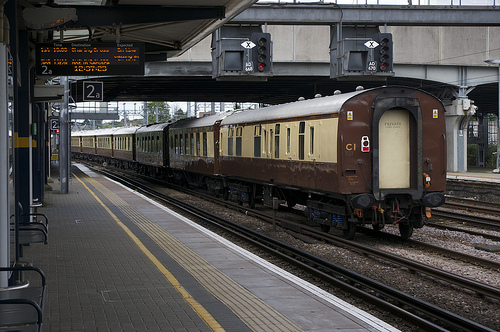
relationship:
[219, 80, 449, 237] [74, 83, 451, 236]
car on car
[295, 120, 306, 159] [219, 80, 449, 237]
window on car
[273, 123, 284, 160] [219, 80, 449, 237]
window on car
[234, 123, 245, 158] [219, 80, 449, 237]
window on car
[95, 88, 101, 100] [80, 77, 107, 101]
letter on sign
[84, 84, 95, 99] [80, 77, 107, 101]
number on sign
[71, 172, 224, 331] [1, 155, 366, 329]
line painted on platform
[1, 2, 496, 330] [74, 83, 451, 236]
station for train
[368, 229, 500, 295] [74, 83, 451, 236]
tracks for train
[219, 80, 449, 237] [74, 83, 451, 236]
car on train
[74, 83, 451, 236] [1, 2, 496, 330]
train leaving station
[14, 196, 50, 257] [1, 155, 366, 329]
bench on platform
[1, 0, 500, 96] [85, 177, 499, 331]
overpass crossing tracks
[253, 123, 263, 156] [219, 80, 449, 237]
window on car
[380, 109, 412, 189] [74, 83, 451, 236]
door on train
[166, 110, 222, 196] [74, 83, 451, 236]
car on train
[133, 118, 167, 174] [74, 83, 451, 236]
car on train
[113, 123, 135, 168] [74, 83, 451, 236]
car on train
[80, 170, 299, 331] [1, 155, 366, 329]
lines painted on platform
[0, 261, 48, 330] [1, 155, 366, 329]
bench on platform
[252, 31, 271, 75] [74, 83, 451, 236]
signal above train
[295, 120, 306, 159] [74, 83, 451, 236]
window on train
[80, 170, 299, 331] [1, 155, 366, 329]
lines on platform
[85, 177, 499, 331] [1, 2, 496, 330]
tracks at station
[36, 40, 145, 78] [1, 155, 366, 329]
sign over platform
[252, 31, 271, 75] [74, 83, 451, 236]
signal over train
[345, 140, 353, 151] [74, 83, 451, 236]
letter on train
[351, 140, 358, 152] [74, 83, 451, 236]
letter on train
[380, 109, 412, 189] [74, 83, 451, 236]
door of train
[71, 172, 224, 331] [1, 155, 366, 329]
line on platform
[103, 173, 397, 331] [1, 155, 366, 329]
line on platform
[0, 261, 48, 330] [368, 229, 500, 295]
bench left of tracks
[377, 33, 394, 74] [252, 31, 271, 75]
light right of signal